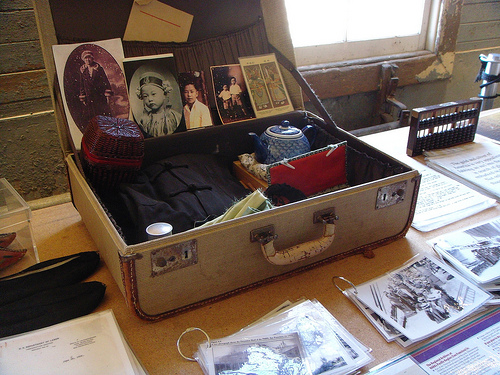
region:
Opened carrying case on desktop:
[30, 1, 420, 323]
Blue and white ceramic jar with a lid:
[263, 119, 307, 164]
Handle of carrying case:
[246, 205, 337, 268]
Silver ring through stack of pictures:
[176, 326, 212, 361]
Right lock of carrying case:
[146, 240, 196, 276]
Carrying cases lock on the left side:
[375, 180, 408, 207]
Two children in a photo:
[209, 62, 256, 122]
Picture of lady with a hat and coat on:
[50, 37, 126, 152]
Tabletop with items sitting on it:
[3, 108, 498, 374]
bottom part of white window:
[280, 2, 449, 76]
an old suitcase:
[33, 6, 431, 273]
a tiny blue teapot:
[244, 110, 314, 168]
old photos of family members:
[132, 58, 294, 134]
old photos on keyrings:
[333, 256, 488, 336]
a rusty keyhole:
[152, 238, 203, 272]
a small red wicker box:
[82, 113, 149, 193]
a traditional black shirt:
[108, 140, 243, 225]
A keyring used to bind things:
[170, 318, 218, 369]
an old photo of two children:
[203, 60, 252, 130]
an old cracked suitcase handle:
[249, 210, 338, 269]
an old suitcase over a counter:
[1, 0, 498, 371]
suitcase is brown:
[30, 0, 430, 319]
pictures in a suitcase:
[51, 22, 304, 163]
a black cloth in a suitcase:
[108, 148, 248, 232]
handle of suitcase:
[247, 208, 345, 271]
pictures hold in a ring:
[327, 243, 495, 348]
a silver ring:
[329, 269, 374, 309]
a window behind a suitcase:
[44, 3, 466, 251]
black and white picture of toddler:
[120, 59, 187, 140]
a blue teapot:
[239, 112, 326, 174]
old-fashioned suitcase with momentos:
[26, 0, 424, 321]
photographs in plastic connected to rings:
[177, 215, 497, 371]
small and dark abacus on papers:
[400, 90, 480, 155]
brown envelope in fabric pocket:
[42, 2, 263, 52]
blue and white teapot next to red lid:
[230, 111, 347, 201]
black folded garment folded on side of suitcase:
[87, 136, 252, 241]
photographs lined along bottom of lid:
[60, 30, 290, 140]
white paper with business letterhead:
[2, 305, 147, 370]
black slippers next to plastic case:
[2, 156, 108, 341]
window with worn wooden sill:
[281, 2, 469, 93]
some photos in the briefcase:
[51, 23, 420, 255]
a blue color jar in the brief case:
[251, 119, 318, 160]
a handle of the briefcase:
[253, 223, 340, 268]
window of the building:
[297, 0, 467, 97]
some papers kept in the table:
[7, 318, 149, 373]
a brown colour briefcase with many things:
[36, 0, 449, 327]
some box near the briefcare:
[1, 179, 43, 275]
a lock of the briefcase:
[376, 183, 411, 208]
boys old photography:
[216, 73, 249, 121]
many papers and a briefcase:
[42, 128, 497, 373]